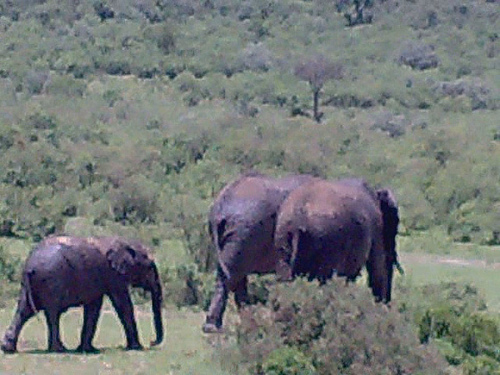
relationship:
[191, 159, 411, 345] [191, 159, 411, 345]
elephant side elephant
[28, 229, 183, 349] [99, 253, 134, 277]
elephant has ear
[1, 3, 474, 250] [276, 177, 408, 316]
trees behind elephant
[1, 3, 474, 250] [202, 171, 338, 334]
trees behind elephant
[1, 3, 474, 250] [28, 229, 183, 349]
trees behind elephant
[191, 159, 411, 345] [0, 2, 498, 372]
elephant in field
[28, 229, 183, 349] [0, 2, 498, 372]
elephant in field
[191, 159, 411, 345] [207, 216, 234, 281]
elephant has tail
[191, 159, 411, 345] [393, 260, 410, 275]
elephant has tusk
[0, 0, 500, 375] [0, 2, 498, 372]
bushes on field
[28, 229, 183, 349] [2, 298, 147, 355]
elephant has legs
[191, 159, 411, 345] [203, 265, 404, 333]
elephant has legs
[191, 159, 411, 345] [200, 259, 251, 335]
elephant has legs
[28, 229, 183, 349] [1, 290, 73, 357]
elephant has legs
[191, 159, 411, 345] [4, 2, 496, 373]
elephant on grass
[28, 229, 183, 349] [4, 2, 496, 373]
elephant on grass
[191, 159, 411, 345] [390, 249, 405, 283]
elephant has tusk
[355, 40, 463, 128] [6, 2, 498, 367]
bushes on ground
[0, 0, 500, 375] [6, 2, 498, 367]
bushes on ground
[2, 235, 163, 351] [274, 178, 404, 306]
baby elephant with big elephant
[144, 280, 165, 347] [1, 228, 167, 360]
trunk on baby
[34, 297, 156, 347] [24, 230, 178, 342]
legs on baby elephant